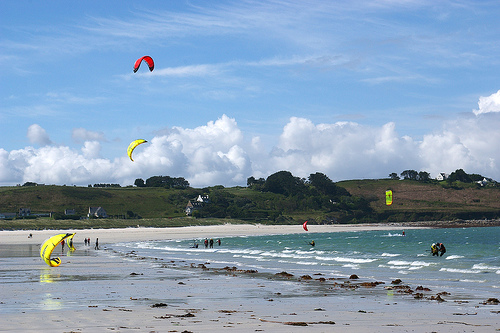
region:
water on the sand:
[27, 292, 62, 315]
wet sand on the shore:
[49, 267, 126, 296]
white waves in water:
[314, 247, 409, 267]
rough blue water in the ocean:
[343, 243, 383, 254]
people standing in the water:
[193, 228, 221, 253]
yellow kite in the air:
[380, 177, 400, 217]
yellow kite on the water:
[30, 231, 81, 266]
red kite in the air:
[295, 212, 315, 229]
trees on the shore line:
[259, 170, 360, 210]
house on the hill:
[185, 191, 231, 210]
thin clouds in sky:
[5, 4, 497, 116]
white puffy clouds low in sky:
[2, 93, 499, 186]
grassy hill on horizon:
[3, 179, 493, 233]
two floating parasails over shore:
[126, 54, 154, 161]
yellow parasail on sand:
[39, 232, 73, 267]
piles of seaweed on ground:
[122, 258, 494, 331]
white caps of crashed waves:
[149, 242, 498, 281]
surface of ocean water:
[176, 226, 498, 268]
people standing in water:
[192, 237, 223, 249]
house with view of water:
[186, 195, 222, 220]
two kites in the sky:
[124, 49, 159, 166]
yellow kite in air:
[122, 133, 147, 161]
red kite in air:
[129, 52, 156, 75]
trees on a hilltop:
[383, 163, 497, 193]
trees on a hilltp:
[11, 173, 191, 197]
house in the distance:
[180, 188, 212, 220]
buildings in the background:
[1, 201, 111, 223]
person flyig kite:
[301, 218, 318, 248]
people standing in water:
[428, 241, 445, 258]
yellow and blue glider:
[39, 231, 74, 266]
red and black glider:
[133, 53, 155, 74]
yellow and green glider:
[385, 189, 393, 207]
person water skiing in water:
[400, 226, 407, 236]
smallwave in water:
[316, 254, 378, 264]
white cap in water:
[443, 252, 465, 259]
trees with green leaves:
[133, 175, 189, 188]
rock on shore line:
[350, 274, 359, 279]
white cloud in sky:
[471, 88, 498, 117]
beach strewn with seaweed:
[17, 220, 477, 330]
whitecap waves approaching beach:
[134, 238, 491, 293]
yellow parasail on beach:
[38, 217, 105, 289]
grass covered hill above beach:
[203, 180, 498, 232]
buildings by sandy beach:
[1, 200, 177, 252]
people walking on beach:
[46, 235, 120, 264]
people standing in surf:
[194, 231, 239, 254]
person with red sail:
[297, 223, 326, 258]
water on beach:
[1, 242, 197, 332]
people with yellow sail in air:
[380, 188, 456, 263]